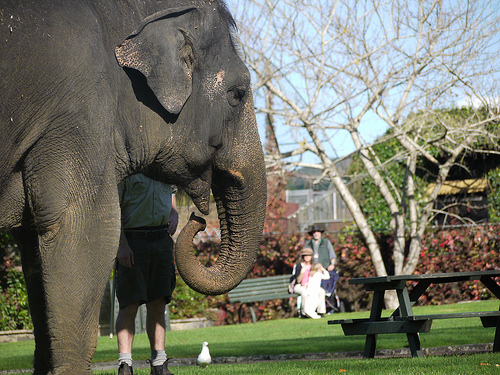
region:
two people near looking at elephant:
[240, 222, 342, 314]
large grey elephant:
[26, 0, 271, 358]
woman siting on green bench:
[289, 241, 325, 318]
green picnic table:
[337, 239, 495, 356]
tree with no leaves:
[338, 1, 485, 335]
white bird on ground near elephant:
[185, 334, 239, 369]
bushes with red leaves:
[365, 218, 495, 302]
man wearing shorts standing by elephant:
[112, 151, 193, 366]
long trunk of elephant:
[163, 93, 275, 304]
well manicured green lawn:
[257, 311, 323, 355]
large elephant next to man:
[3, 1, 295, 369]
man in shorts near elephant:
[113, 181, 187, 373]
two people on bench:
[293, 219, 346, 349]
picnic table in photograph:
[313, 262, 493, 364]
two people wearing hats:
[286, 205, 341, 268]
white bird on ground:
[190, 331, 238, 366]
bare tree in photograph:
[239, 1, 496, 268]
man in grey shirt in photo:
[102, 166, 210, 242]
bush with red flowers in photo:
[346, 227, 498, 330]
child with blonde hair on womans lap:
[298, 251, 330, 337]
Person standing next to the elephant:
[112, 169, 187, 372]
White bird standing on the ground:
[193, 337, 216, 370]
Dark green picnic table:
[328, 270, 499, 360]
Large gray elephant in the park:
[4, 0, 275, 373]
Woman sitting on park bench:
[288, 249, 328, 323]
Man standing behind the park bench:
[304, 222, 336, 271]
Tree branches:
[259, 17, 496, 104]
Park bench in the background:
[225, 272, 290, 324]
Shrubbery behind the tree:
[427, 231, 499, 276]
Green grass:
[236, 325, 307, 350]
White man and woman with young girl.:
[281, 219, 355, 320]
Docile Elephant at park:
[20, 5, 280, 366]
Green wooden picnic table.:
[315, 260, 495, 357]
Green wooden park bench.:
[217, 265, 288, 320]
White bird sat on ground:
[185, 340, 230, 365]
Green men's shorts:
[115, 225, 173, 310]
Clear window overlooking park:
[251, 188, 498, 372]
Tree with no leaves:
[242, 1, 499, 332]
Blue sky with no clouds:
[281, 12, 481, 117]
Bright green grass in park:
[278, 248, 498, 373]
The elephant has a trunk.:
[170, 152, 271, 300]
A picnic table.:
[320, 250, 498, 340]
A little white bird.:
[185, 333, 222, 373]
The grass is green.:
[228, 316, 328, 348]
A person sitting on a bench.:
[251, 245, 331, 317]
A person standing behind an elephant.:
[110, 155, 190, 373]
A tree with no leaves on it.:
[271, 0, 492, 265]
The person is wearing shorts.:
[115, 233, 167, 348]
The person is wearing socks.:
[111, 345, 167, 360]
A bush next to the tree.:
[355, 220, 497, 268]